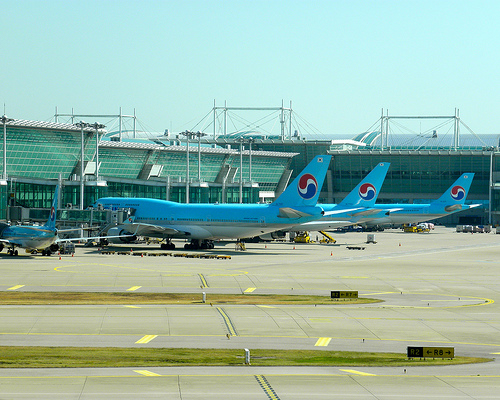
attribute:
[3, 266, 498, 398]
taxiways — airport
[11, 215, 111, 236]
stabilizer — horizontal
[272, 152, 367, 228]
tail — jet's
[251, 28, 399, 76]
sky — clear, blue, cloudless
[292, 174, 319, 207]
logo — red, white, blue 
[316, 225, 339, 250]
stairs — yellow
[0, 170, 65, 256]
plane — bright, light blue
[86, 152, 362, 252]
plane — bright, light blue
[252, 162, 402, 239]
plane — bright, light blue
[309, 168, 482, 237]
plane — bright, light blue, very large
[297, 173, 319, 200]
logo — red, white, blue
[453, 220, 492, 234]
carts — empty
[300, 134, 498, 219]
building — airport, terminal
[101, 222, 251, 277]
cart — line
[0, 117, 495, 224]
building — green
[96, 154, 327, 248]
plane — very large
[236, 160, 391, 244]
plane — very large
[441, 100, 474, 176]
poles — metal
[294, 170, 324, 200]
symbol — red, white, blue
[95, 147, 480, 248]
planes — not flying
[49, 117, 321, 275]
plane — blue 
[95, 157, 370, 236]
plane — blue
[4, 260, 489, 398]
lines — yellow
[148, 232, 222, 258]
gears — jet's, rear, landing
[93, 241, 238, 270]
carriers — empty cart